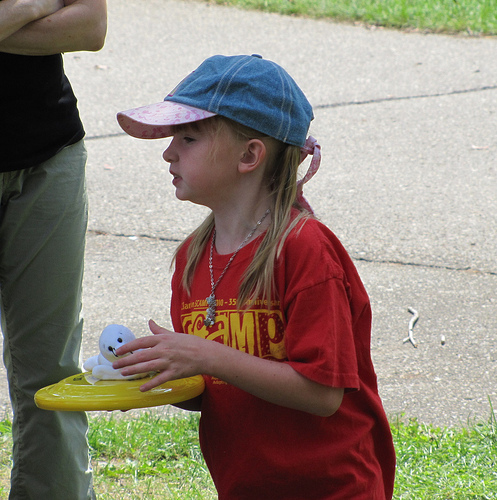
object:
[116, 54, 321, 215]
cap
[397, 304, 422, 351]
twig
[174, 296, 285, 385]
letters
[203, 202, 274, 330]
necklace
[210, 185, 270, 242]
girl's neck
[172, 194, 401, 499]
red shirt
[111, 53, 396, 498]
girl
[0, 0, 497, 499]
ground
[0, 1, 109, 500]
adult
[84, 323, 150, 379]
stuffed toy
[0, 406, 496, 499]
grass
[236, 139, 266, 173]
ear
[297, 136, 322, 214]
strap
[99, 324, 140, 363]
face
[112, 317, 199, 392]
hands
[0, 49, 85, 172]
shirt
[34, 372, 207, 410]
frisbee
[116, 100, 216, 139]
rim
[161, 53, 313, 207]
head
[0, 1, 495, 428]
road